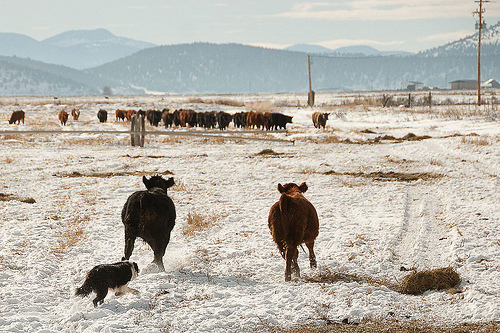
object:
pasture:
[0, 88, 499, 332]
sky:
[0, 0, 498, 50]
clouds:
[257, 0, 499, 21]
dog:
[74, 256, 141, 308]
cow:
[267, 182, 319, 282]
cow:
[121, 173, 176, 270]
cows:
[58, 109, 70, 126]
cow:
[8, 110, 25, 126]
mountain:
[0, 23, 499, 99]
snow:
[35, 149, 500, 331]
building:
[449, 79, 478, 89]